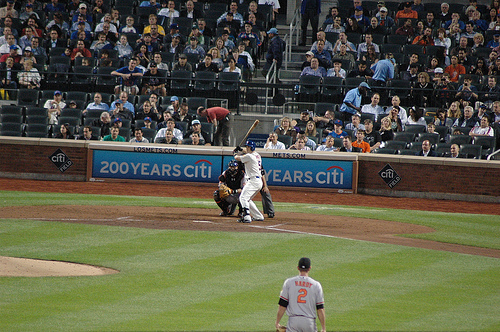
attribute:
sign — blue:
[99, 149, 225, 185]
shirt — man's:
[278, 270, 326, 317]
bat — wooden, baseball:
[218, 115, 272, 157]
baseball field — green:
[0, 175, 494, 329]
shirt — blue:
[338, 88, 363, 112]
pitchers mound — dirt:
[2, 254, 123, 276]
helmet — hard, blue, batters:
[243, 140, 254, 152]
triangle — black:
[46, 150, 73, 174]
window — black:
[86, 143, 226, 188]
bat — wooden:
[232, 118, 260, 156]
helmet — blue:
[234, 128, 256, 157]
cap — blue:
[244, 140, 258, 150]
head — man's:
[245, 143, 259, 152]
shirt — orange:
[349, 140, 369, 150]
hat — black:
[298, 256, 312, 269]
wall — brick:
[2, 131, 479, 201]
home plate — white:
[192, 213, 212, 224]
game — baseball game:
[0, 140, 485, 330]